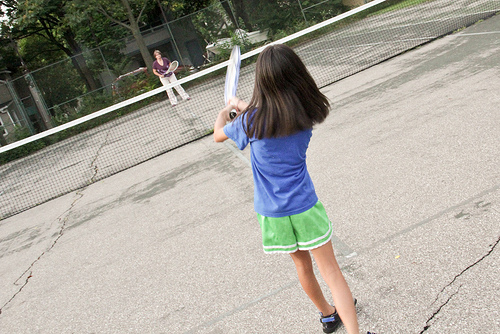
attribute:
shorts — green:
[252, 201, 337, 259]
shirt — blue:
[221, 112, 324, 221]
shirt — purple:
[152, 61, 175, 79]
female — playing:
[204, 35, 362, 331]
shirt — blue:
[226, 104, 329, 220]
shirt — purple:
[150, 55, 171, 80]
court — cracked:
[2, 4, 494, 331]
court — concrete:
[70, 95, 455, 299]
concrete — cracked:
[15, 147, 239, 291]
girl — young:
[196, 47, 406, 322]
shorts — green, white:
[229, 183, 379, 256]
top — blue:
[205, 107, 386, 246]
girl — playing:
[158, 38, 433, 311]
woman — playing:
[122, 41, 191, 103]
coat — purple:
[137, 54, 182, 86]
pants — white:
[145, 69, 207, 112]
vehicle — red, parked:
[84, 60, 159, 116]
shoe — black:
[284, 300, 352, 324]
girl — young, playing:
[197, 22, 412, 277]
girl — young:
[197, 51, 385, 331]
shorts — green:
[251, 186, 336, 267]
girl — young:
[149, 43, 409, 323]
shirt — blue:
[175, 82, 341, 204]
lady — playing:
[119, 46, 216, 120]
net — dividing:
[26, 35, 494, 127]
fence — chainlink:
[2, 28, 273, 117]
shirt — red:
[138, 52, 182, 72]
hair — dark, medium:
[238, 36, 327, 122]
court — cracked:
[18, 137, 148, 277]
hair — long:
[244, 45, 326, 142]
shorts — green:
[257, 217, 340, 248]